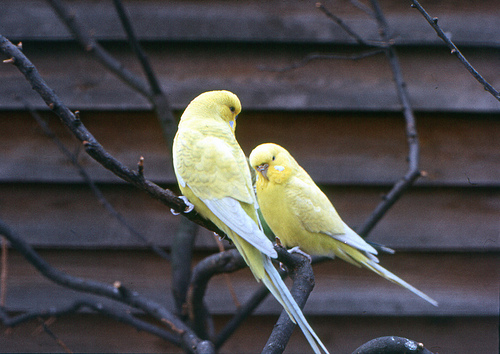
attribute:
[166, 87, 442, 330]
birds — yellow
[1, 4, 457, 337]
branch — bare